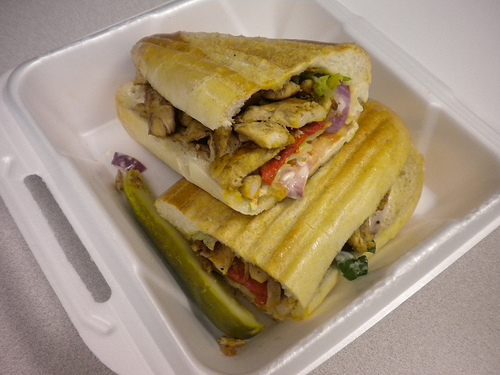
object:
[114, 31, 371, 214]
sandwich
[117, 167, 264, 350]
pickle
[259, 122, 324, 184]
food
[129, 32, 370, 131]
bread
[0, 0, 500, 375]
box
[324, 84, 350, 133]
food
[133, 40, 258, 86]
lines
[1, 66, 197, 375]
foam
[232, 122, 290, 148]
meat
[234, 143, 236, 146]
pepper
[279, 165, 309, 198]
onion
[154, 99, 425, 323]
bottom half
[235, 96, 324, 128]
chicken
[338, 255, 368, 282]
lettuce